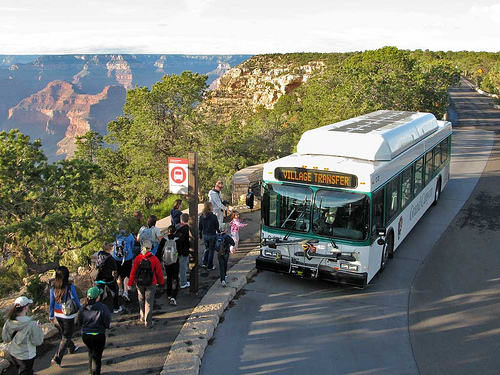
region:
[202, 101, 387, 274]
the bus is white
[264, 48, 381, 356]
the bus is white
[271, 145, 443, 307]
the bus is white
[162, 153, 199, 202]
sign for the bus stop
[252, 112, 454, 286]
green and white bus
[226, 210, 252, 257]
a little girl in pink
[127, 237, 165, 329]
a woman wearing a backpack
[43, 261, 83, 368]
a woman with blue shirt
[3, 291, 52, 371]
woman with white cap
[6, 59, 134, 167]
beautiful mountain range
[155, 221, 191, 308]
a person with a grey backpack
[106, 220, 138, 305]
someone wearing a blue shirt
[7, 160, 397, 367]
several people getting on the bus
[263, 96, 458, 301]
bus on side of road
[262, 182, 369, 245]
front windshield of bus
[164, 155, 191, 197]
sign on side of road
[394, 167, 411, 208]
window on side of bus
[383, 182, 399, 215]
window on side of bus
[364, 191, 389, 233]
window on side of bus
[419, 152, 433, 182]
window on side of bus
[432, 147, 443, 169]
window on side of bus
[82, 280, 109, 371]
person in green cap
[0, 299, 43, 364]
person in white cap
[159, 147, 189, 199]
Red and white bus stop sign.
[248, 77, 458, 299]
Large white bus.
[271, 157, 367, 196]
Route information on bus.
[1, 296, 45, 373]
Woman walking toward bus with white baseball hat.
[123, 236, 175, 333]
Woman in red jacket with black backpack.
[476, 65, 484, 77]
Yellow street sign.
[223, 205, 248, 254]
Little girl in pink shirt.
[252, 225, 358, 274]
Bike racks at the front of the bus.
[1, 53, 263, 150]
Barren and rocky mountains.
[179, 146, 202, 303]
Wooden pole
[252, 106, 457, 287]
a long white bus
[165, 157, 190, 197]
a red and white sign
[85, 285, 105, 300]
a green baseball cap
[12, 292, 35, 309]
a white baseball cap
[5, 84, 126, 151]
a rock mountain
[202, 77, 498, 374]
a paved road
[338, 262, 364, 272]
the headlight of a bus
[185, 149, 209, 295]
a tall wooden pole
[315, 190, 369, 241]
the window of a bus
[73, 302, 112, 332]
a woman's blue jacket